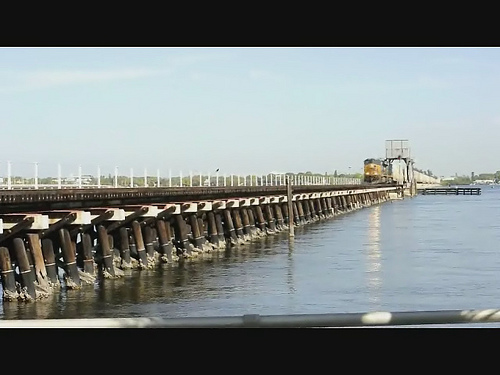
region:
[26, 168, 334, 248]
brown wooden bridge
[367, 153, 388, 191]
yellow train engine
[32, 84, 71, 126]
white clouds in blue sky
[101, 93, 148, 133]
white clouds in blue sky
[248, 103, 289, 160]
white clouds in blue sky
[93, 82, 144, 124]
white clouds in blue sky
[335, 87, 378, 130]
white clouds in blue sky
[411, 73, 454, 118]
white clouds in blue sky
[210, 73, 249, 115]
white clouds in blue sky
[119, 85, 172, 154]
white clouds in blue sky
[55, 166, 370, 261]
long wooden pier on water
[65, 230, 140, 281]
wooden pylons of pier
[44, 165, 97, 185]
white fence on side of pier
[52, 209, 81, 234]
wooden support beams sticking out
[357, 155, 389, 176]
yellow and black train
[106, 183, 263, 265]
wooden bridge across water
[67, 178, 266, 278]
wooden train bridge on water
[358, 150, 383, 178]
front end of long train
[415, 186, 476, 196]
wooden pier on water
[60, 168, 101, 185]
buildings in background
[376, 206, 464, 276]
the water is dark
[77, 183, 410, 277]
the bridge is large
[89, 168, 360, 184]
the fence is over the bridge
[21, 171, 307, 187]
the fence is white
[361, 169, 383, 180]
the train has headlights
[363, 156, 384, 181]
the train is yellow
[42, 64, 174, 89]
the cloud is thin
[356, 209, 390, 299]
the reflection s on the water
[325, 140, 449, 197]
the train is on the bridge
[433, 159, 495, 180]
the buildings are on the shore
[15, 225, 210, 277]
pylons below the bridge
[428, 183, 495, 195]
a pier in the distance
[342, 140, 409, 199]
a train on the bridge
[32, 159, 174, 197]
white poles line the bridge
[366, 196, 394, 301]
a reflection of light on water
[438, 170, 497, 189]
landscape in the distance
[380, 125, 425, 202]
a building on the bridge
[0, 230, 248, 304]
rocks and barnicles on the pylons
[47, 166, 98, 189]
a building in the distance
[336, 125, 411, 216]
the train is yellow and black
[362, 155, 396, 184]
train near the water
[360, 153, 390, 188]
train on the train tracks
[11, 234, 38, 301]
wooden support under rail bridge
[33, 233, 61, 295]
wooden support under rail bridge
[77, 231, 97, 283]
wooden support under rail bridge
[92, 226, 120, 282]
wooden support under rail bridge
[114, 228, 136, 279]
wooden support under rail bridge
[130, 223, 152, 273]
wooden support under rail bridge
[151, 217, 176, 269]
wooden support under rail bridge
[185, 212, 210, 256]
wooden support under rail bridge